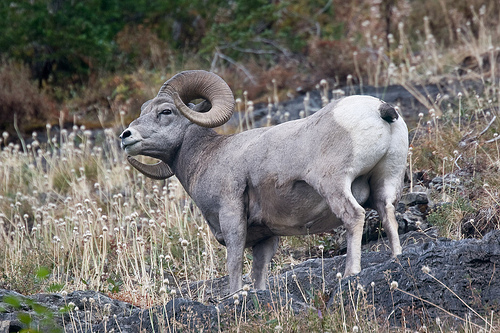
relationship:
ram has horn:
[122, 68, 431, 305] [162, 75, 243, 123]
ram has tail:
[122, 68, 431, 305] [379, 101, 403, 128]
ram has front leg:
[122, 68, 431, 305] [223, 239, 249, 296]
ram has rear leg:
[122, 68, 431, 305] [328, 202, 369, 276]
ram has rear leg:
[122, 68, 431, 305] [375, 195, 405, 276]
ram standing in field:
[122, 68, 431, 305] [19, 138, 499, 294]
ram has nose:
[122, 68, 431, 305] [114, 127, 139, 141]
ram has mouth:
[122, 68, 431, 305] [111, 138, 151, 152]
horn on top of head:
[162, 75, 243, 123] [117, 94, 221, 164]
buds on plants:
[42, 199, 146, 225] [9, 223, 199, 307]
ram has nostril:
[122, 68, 431, 305] [126, 132, 130, 137]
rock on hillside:
[444, 56, 489, 92] [29, 34, 499, 206]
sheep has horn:
[125, 59, 434, 247] [162, 75, 243, 123]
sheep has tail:
[125, 59, 434, 247] [379, 101, 403, 128]